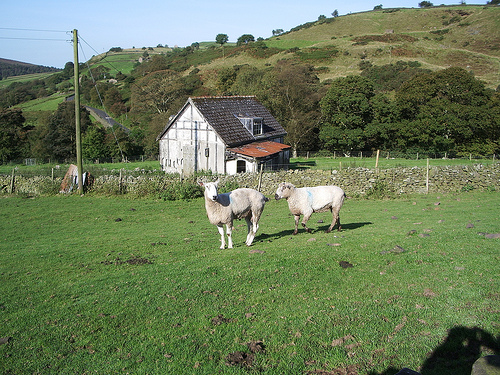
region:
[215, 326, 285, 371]
Pot hole in the grass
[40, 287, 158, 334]
Very green and short grass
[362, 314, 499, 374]
Shadow in the grass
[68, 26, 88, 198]
A tall telephone pole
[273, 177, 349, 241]
A sheep walking in the grass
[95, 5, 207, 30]
Clear sky with no clouds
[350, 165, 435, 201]
A long stone wall running in the yard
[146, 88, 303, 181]
A large shack in the field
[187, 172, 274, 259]
An alert sheep in the field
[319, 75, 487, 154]
A lining a lush green trees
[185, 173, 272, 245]
this is a sheep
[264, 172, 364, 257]
this is a sheep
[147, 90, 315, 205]
this is a house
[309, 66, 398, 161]
this is a tree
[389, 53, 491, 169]
this is a tree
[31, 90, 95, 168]
this is a tree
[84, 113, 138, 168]
this is a tree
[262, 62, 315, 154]
this is a tree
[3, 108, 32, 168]
this is a tree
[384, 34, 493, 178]
this is a tree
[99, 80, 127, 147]
Orange hanging down from the trees.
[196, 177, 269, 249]
a sheep standing on the grass.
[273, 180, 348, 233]
A white sheep on the grass.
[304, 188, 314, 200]
A blue spot on the sheep.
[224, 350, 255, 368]
A small pile of dirt.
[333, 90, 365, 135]
Part of a tree.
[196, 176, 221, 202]
The head of the sheep.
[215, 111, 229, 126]
Part of the roof.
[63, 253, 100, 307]
part of the grass.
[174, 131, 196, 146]
Part of the house.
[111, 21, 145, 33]
Part of the sky.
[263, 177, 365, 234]
This is a sheep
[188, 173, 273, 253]
This is a sheep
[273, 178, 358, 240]
This is a sheep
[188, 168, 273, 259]
This is a sheep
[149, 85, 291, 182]
This is a house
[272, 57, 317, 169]
This is a tree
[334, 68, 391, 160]
This is a tree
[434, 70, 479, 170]
This is a tree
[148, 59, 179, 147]
This is a tree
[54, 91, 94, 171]
This is a tree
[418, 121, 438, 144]
green leaves on the tree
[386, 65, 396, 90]
green leaves on the tree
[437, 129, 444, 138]
green leaves on the tree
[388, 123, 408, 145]
green leaves on the tree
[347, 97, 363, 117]
green leaves on the tree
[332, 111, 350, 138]
green leaves on the tree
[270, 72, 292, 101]
green leaves on the tree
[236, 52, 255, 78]
green leaves on the tree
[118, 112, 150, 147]
green leaves on the tree